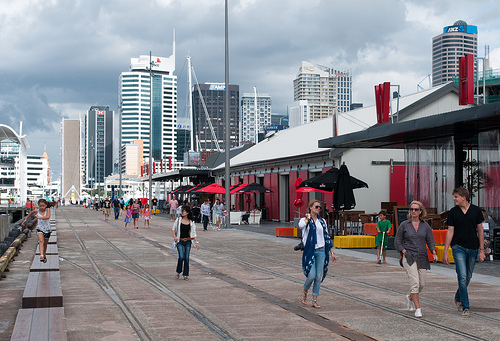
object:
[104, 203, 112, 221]
pedestrians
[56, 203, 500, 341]
walkway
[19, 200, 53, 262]
girl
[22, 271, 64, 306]
bench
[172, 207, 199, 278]
woman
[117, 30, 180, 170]
skyscrapers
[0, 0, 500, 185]
clouds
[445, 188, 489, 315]
man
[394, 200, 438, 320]
walking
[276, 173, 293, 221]
doors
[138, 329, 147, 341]
metal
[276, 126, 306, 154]
white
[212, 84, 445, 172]
roof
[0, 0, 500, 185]
sky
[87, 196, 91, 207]
people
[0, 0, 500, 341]
background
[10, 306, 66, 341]
benches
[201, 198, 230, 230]
couple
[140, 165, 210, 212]
businesses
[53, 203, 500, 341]
street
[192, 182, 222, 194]
umbrellas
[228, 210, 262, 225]
tables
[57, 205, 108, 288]
tracks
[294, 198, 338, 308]
woman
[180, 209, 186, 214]
sunglasses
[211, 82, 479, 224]
building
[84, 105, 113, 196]
buildings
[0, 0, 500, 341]
city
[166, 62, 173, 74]
white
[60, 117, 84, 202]
building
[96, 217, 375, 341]
boardwalk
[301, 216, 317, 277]
scarf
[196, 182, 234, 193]
red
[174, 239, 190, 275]
jeans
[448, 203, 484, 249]
shirt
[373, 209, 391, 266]
boy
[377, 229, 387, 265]
scooter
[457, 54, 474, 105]
red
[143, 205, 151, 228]
girl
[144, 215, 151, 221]
shorts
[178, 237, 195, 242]
belt